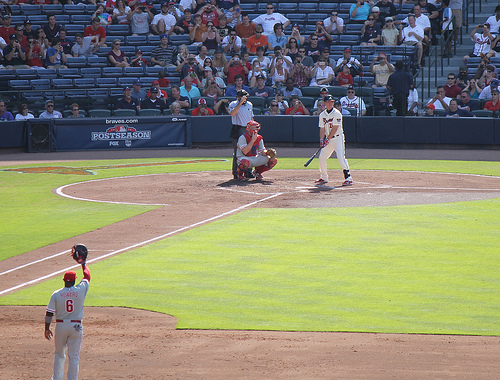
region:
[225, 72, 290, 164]
the helmet is plastic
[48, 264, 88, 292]
this is a hat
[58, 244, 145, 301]
the hat is red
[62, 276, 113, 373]
this is a number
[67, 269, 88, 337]
the number is red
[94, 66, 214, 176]
this is the stands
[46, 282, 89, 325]
red and white jersey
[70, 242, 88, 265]
black leather baseball mitt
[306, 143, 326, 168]
black metal baseball bat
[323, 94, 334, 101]
black plastic batting helmet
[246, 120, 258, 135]
red plastic catchers mask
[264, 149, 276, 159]
brown leather catchers mitt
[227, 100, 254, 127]
blue cotton polo shirt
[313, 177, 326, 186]
red and white cleats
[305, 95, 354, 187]
man holding baseball bat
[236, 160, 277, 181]
red padded knee pads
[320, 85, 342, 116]
head of a person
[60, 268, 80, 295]
head of a person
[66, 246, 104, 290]
arm of a person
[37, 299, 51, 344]
arm of a person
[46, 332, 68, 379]
leg of a person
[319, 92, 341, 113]
head of a person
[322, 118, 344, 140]
arm of a person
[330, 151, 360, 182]
leg of a person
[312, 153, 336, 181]
leg of a person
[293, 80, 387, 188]
batter at the plate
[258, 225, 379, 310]
green grass in the infield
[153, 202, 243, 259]
white line on the ground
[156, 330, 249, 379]
dirt on the ground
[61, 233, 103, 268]
glove in the air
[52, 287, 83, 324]
number on back of jersey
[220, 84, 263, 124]
umpire behind the catcher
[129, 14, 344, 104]
fans in the audience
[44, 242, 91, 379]
Baseball player with his mitt in the air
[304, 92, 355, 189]
Batter at the home plate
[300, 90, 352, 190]
Batter holding his bat low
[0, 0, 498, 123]
People watching a baseball game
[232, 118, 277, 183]
Catcher wearing red padding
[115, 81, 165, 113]
Two men in navy blue hats and shirts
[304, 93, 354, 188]
Baseball player in a white uniform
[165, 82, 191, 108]
Man sitting with his arms crossed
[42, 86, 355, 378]
Four baseball players playing baseball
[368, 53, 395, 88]
Man taking pictures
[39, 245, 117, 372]
The player with number 6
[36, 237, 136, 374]
A player with number 6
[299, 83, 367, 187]
The player batting the ball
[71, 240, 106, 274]
glove is on persons hand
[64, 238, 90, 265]
glove is black in color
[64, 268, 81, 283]
player is wearing a hat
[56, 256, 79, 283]
hat is red in color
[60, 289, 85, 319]
person has number on back of jersey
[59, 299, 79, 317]
number on jersey is red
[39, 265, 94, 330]
uniform on player is gray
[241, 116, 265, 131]
catcher is wearing a helmet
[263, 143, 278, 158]
catcher is wearing a mitt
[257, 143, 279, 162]
mitt is brown in color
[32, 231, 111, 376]
man raising one hand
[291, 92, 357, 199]
man holding baseball bat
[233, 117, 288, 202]
man croching on base ball field